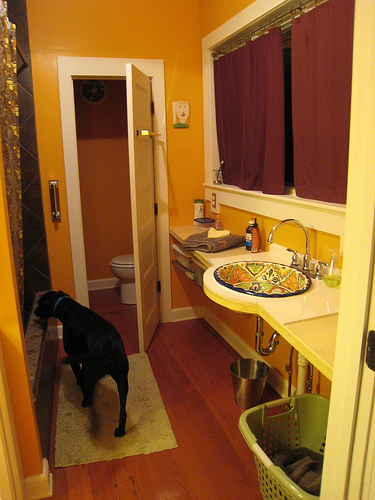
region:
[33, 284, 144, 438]
black labrador retreiver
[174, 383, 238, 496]
dark colored hard wood floor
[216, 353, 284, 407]
silver metal waste paper basket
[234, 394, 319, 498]
green laundry basket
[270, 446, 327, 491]
dirty laundry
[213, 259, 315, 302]
yellow mosaic tile bathroom sink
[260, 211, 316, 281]
silver bathroom sink faucet and handles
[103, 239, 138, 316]
white porcelain toilet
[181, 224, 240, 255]
towel on bathroom cabinet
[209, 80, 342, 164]
red curtains in the window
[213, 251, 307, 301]
a painted bathroom sink basin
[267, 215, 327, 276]
a chrome bathroom faucet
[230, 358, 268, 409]
a metal trash can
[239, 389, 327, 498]
a green laundry basket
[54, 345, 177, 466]
a bath mat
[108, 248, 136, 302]
a porcelain toilet bowl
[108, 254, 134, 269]
a white plastic toilet seat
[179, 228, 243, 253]
a folded brown towel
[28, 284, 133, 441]
a large black dog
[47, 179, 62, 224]
a chrome handle bar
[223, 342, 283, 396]
bucket under the sink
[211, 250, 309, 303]
multi colored sink in bathroom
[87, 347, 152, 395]
black tail of dog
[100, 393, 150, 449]
right leg of dog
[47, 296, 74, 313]
blue collar on black dog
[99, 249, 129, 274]
toilet rim in back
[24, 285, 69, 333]
head of black dog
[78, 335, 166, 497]
beige bathroom rug under dog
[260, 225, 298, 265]
head of stainless steel faucet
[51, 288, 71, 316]
the dog is wearing a collar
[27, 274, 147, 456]
the dog is black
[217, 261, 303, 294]
the sink is multi-colored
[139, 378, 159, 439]
the rug is white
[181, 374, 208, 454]
the floor is brown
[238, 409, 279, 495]
the basket is green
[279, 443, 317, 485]
clothes are in the basket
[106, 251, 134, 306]
the toilet is white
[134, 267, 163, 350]
the door is open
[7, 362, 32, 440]
the wall is orange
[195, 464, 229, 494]
floors are made out of harwood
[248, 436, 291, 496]
basket is sitting on the floor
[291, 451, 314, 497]
clothes are in the laundry basket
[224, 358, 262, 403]
silver tin can under the sink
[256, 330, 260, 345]
long silver pipe from the sink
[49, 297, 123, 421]
black dog standing in bathroom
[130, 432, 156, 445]
beigh rug on the floor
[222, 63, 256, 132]
red curtains hanging to window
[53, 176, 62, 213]
a towel holder hanging off the wall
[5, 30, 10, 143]
shower curtains open to the shower